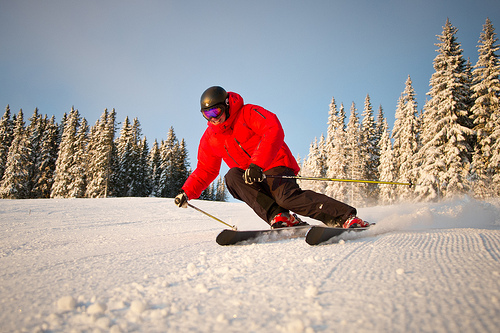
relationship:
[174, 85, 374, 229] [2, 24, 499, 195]
man on ground snow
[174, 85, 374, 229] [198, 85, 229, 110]
man wearing helmet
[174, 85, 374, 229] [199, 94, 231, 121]
man wearing goggles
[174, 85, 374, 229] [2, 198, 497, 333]
man on snow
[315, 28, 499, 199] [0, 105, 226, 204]
evergreen trees in background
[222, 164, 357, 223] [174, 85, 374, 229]
sweatpants on man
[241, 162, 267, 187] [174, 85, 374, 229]
glove on man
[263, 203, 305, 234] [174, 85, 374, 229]
left foot of a man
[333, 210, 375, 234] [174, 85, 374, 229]
right foot of a man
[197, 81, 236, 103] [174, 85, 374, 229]
helmet of man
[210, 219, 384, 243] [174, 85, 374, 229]
skis on man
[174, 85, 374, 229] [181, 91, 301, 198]
man wearing jacket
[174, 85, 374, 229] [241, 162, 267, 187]
man wearing glove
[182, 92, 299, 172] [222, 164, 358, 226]
man wearing sweatpants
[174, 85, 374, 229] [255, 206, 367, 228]
man wearing shoes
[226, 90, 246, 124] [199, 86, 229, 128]
red hood on a helmet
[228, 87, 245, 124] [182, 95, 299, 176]
red hood on a jacket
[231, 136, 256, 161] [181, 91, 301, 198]
black zipper on a jacket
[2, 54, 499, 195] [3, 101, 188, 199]
snow on pine trees